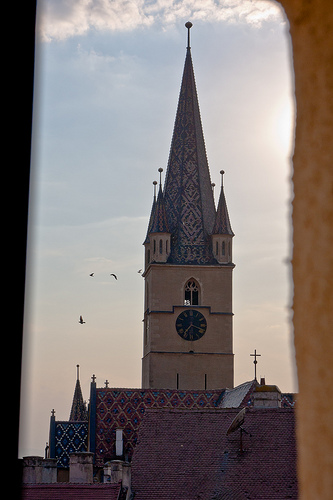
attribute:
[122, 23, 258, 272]
top — decorated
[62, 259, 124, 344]
birds — flying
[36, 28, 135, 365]
sky — blue, cloudy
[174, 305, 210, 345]
clock — large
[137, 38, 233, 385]
tower — narrow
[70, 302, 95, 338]
bird — black, flying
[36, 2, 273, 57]
clouds — patchy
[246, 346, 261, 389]
cross — stone, small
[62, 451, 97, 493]
chimney — tallest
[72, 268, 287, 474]
church — beautiful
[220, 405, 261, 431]
dish — grey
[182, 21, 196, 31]
ball — round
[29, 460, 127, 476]
smokestacks — stone